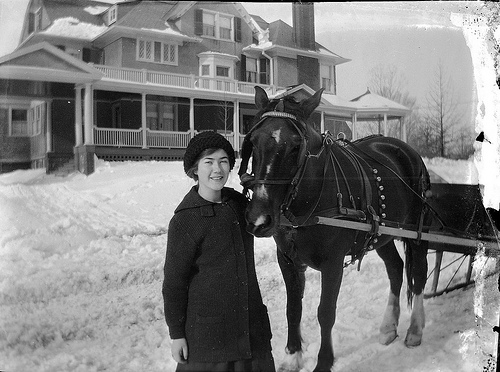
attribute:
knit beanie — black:
[183, 130, 238, 175]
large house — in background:
[0, 2, 417, 177]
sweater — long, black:
[159, 182, 276, 361]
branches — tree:
[442, 87, 462, 152]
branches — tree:
[418, 117, 438, 154]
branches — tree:
[376, 62, 433, 141]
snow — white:
[1, 155, 497, 367]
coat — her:
[163, 195, 273, 353]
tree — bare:
[424, 60, 472, 160]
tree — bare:
[407, 112, 445, 157]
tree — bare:
[355, 70, 415, 141]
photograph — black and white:
[1, 2, 498, 370]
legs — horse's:
[270, 263, 350, 364]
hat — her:
[181, 122, 242, 186]